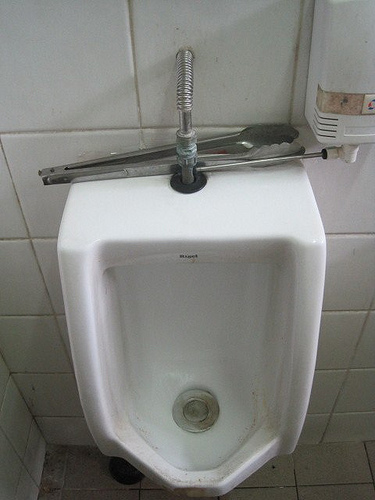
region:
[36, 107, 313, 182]
spatula prongs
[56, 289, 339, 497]
urinal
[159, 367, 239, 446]
urinal hole is closed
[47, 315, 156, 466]
The urinal is white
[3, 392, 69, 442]
walls are lined with tile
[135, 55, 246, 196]
parts are missing from the urinal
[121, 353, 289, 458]
Nothing is sitting in the urinal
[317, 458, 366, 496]
The floor is made of tile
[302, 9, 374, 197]
A machine is to the right of the urinal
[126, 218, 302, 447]
The urinal walls cast a shadow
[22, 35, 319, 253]
Kitchen tongs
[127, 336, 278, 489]
Urinal with no water.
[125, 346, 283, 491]
A dirty urinal.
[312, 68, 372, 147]
Urinal cleanser for cleaning.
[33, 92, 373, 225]
Kitchen tongs on the urinal.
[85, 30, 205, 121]
White tile in the bathroom.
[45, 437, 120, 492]
Floor tiles in the bathroom.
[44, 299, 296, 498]
White porcelain urinal in the bathroom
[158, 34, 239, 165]
Waterline coming out of the wall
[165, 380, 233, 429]
Urinal drain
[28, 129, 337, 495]
This is a urinal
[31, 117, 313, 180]
This is a pair of tongs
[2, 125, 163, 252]
This is a tile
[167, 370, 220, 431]
This is a drain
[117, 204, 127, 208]
This is the color white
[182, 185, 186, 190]
This is the color black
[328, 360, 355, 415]
This is wall cauking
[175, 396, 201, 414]
this is chromed metal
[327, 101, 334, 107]
this is the color brown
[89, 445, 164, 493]
this is a plunger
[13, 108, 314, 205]
Silver metal kitchen utensil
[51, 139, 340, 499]
White porcelain urinal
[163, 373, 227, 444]
Silver metal urinal drain plug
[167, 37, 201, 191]
Silver metal water supply pipe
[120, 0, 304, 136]
White ceramic wall tile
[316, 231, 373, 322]
White ceramic wall tile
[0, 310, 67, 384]
White ceramic wall tile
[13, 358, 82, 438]
White ceramic wall tile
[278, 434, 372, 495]
Brown ceramic floor tile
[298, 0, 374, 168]
White plastic soap dispenser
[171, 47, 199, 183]
Silver hose going to urinal.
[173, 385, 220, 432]
Urinal drain in urinal.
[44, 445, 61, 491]
Crud and dirt in the corner of the floor.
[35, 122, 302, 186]
Silver tongs on the back of the urinal.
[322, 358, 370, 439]
White tiles on the wall by urinal.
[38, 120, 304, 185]
Tongs laying on the back of a urinal.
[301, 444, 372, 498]
Tiles on the floor of the bathroom.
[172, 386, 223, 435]
Silver drain of a urinal.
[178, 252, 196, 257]
Word on the urinal.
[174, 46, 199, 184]
Metal hose for the urinal.